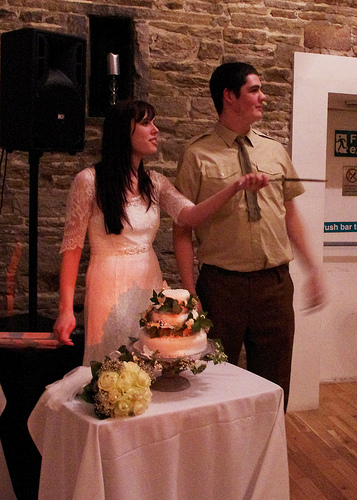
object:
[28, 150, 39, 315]
pole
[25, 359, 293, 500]
table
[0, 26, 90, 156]
speaker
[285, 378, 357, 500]
ground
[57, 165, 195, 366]
dress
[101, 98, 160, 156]
head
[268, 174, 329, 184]
knife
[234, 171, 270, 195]
hand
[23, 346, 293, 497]
tablecloth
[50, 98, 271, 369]
woman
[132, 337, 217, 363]
plate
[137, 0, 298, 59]
wall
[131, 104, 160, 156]
face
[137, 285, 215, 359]
cake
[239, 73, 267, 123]
face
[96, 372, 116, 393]
flower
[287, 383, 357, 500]
floor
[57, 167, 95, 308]
arm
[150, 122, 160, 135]
nose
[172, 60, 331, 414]
man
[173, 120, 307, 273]
shirt